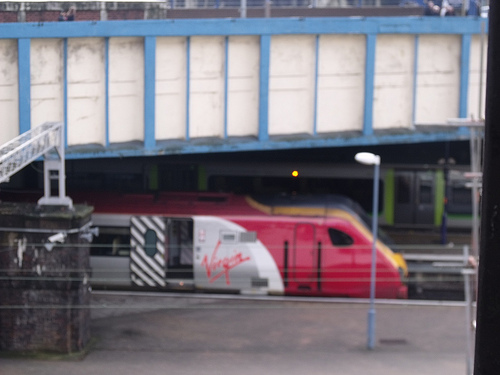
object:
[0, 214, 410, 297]
train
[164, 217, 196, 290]
door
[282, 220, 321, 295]
stripe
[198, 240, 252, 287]
virgin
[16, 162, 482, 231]
train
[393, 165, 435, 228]
doors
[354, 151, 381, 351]
street light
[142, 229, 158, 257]
window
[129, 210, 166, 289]
door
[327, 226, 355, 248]
window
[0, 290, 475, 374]
sidewalk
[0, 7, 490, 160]
bridge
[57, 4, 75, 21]
person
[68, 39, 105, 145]
panel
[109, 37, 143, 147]
panel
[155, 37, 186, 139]
panel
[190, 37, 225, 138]
panel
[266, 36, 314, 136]
panel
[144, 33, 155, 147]
support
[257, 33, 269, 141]
support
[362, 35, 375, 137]
support